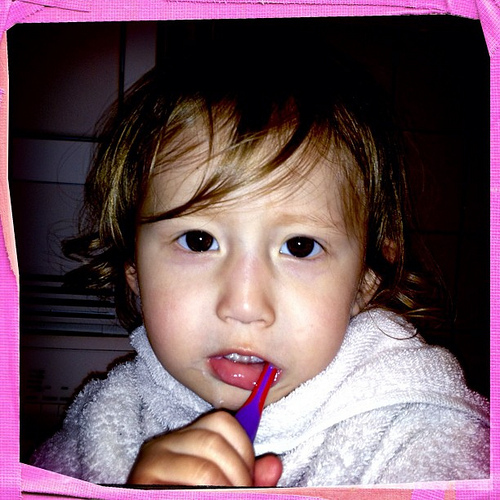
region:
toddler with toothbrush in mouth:
[103, 36, 448, 466]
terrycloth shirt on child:
[310, 321, 472, 472]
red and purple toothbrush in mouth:
[235, 360, 284, 434]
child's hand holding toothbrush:
[129, 406, 291, 488]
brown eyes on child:
[155, 221, 338, 273]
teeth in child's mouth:
[223, 348, 270, 367]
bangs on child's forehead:
[188, 119, 313, 214]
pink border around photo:
[9, 452, 78, 493]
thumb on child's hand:
[252, 451, 297, 484]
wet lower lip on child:
[205, 356, 263, 389]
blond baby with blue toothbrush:
[27, 47, 499, 474]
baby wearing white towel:
[32, 39, 497, 488]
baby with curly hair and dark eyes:
[23, 27, 498, 477]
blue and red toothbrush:
[232, 360, 279, 489]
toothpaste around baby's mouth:
[185, 337, 287, 419]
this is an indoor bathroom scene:
[24, 28, 496, 490]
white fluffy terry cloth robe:
[35, 306, 499, 486]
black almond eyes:
[166, 223, 331, 264]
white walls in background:
[21, 25, 160, 470]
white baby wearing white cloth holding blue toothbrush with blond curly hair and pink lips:
[28, 28, 498, 485]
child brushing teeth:
[71, 55, 436, 456]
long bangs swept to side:
[80, 85, 400, 410]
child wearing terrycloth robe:
[41, 152, 481, 464]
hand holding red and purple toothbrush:
[100, 335, 380, 475]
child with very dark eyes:
[116, 207, 372, 317]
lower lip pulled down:
[190, 325, 297, 405]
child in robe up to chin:
[115, 297, 452, 447]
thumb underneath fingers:
[102, 392, 317, 477]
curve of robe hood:
[280, 380, 485, 451]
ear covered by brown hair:
[345, 215, 402, 343]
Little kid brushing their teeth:
[55, 51, 472, 486]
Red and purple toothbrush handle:
[217, 348, 282, 448]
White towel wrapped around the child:
[35, 334, 492, 486]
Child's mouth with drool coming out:
[182, 350, 295, 422]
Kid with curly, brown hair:
[63, 65, 439, 345]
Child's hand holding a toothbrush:
[102, 356, 297, 498]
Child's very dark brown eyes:
[167, 204, 336, 279]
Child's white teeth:
[218, 348, 273, 370]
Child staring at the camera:
[43, 62, 448, 422]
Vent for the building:
[12, 248, 146, 358]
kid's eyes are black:
[168, 223, 356, 290]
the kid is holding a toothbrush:
[177, 335, 328, 456]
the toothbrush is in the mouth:
[189, 336, 320, 461]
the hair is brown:
[90, 122, 335, 261]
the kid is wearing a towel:
[77, 334, 484, 453]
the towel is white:
[365, 369, 462, 468]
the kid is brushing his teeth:
[110, 331, 350, 473]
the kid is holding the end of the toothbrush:
[73, 374, 345, 496]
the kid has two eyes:
[117, 196, 384, 310]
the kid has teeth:
[206, 343, 318, 397]